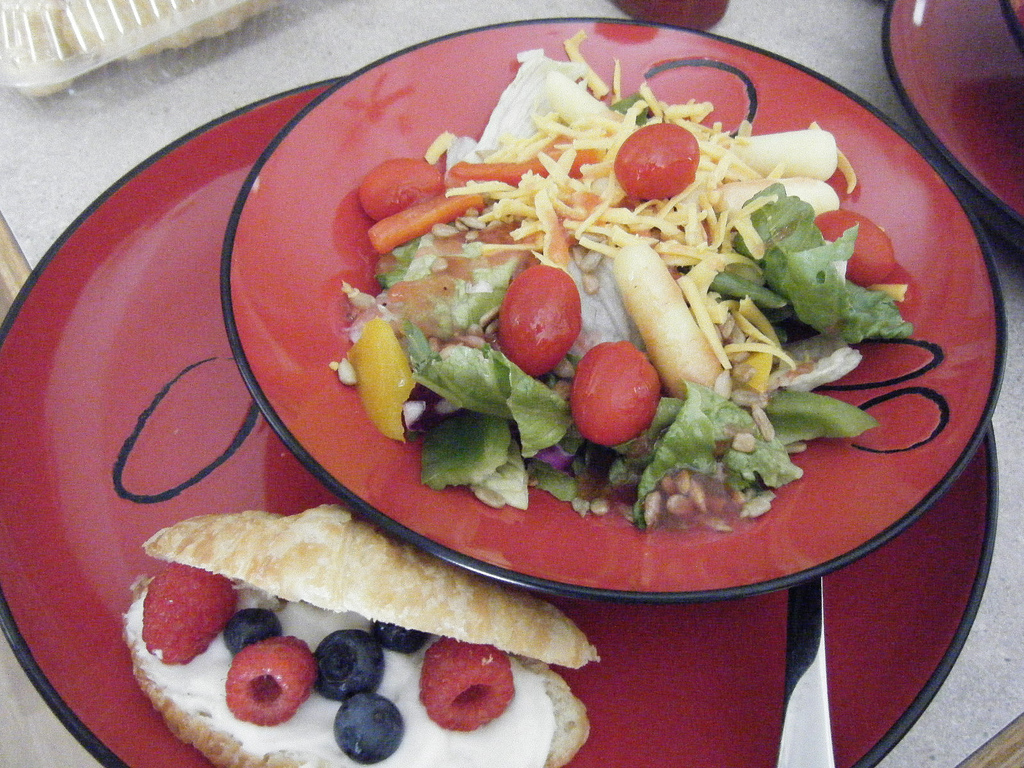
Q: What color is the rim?
A: Black.